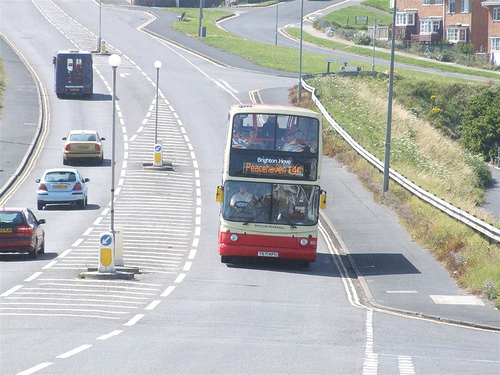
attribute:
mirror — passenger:
[213, 184, 223, 203]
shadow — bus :
[325, 247, 417, 282]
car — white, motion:
[28, 167, 91, 209]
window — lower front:
[273, 192, 309, 219]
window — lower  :
[226, 183, 257, 221]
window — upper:
[245, 116, 305, 154]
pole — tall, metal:
[385, 6, 395, 195]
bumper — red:
[223, 231, 317, 261]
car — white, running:
[65, 130, 103, 163]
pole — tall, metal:
[105, 55, 125, 269]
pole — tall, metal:
[148, 63, 169, 174]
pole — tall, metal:
[95, 3, 107, 54]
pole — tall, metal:
[294, 3, 305, 97]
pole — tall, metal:
[272, 3, 281, 52]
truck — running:
[52, 52, 92, 98]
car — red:
[0, 208, 50, 252]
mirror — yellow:
[215, 183, 222, 203]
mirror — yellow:
[317, 188, 326, 210]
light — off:
[230, 233, 237, 242]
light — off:
[300, 237, 307, 247]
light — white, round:
[111, 54, 121, 66]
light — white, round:
[153, 57, 161, 68]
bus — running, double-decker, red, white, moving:
[218, 106, 325, 267]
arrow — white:
[100, 233, 114, 247]